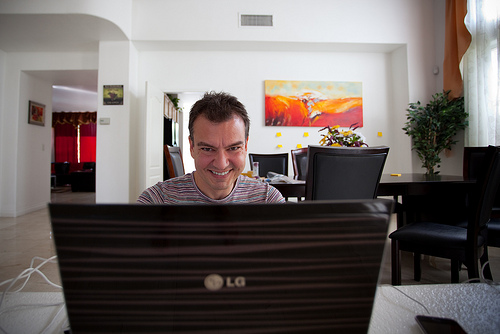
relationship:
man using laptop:
[129, 91, 293, 204] [52, 200, 385, 331]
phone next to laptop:
[413, 315, 471, 332] [52, 200, 385, 331]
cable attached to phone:
[377, 276, 434, 313] [413, 315, 470, 334]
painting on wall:
[265, 80, 362, 128] [144, 55, 398, 176]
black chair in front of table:
[390, 145, 500, 288] [260, 168, 496, 199]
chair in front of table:
[304, 143, 391, 196] [260, 168, 496, 199]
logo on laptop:
[198, 274, 245, 291] [52, 200, 385, 331]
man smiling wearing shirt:
[164, 101, 276, 196] [136, 171, 285, 203]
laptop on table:
[52, 200, 385, 331] [0, 281, 498, 331]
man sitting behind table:
[129, 91, 293, 204] [9, 207, 498, 321]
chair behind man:
[304, 145, 391, 200] [129, 88, 294, 204]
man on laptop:
[129, 88, 294, 204] [46, 191, 397, 331]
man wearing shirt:
[129, 88, 294, 204] [134, 170, 284, 200]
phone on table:
[413, 315, 470, 334] [371, 276, 498, 329]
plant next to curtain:
[403, 87, 470, 179] [433, 0, 477, 142]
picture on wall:
[28, 100, 45, 124] [17, 70, 52, 216]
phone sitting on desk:
[413, 315, 470, 334] [0, 290, 499, 331]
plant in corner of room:
[403, 87, 470, 180] [0, 2, 498, 330]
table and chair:
[380, 172, 475, 220] [307, 145, 389, 200]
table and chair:
[380, 172, 475, 220] [161, 145, 183, 176]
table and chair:
[380, 172, 475, 220] [247, 152, 291, 177]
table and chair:
[380, 172, 475, 220] [290, 146, 307, 178]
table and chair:
[380, 172, 475, 220] [461, 144, 490, 176]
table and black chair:
[380, 172, 475, 220] [390, 145, 500, 288]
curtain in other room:
[80, 115, 95, 161] [46, 84, 96, 204]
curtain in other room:
[51, 115, 94, 160] [46, 84, 96, 204]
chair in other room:
[66, 159, 96, 194] [46, 84, 96, 204]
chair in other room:
[49, 157, 71, 191] [46, 84, 96, 204]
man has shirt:
[129, 88, 294, 204] [136, 168, 288, 202]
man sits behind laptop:
[129, 88, 294, 204] [52, 200, 385, 331]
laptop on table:
[52, 200, 385, 331] [21, 186, 471, 332]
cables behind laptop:
[0, 247, 52, 301] [54, 189, 432, 326]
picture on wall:
[263, 77, 361, 127] [95, 10, 440, 252]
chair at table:
[304, 145, 391, 200] [338, 123, 498, 298]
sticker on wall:
[273, 129, 282, 137] [130, 0, 432, 205]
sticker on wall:
[373, 125, 391, 155] [168, 41, 403, 183]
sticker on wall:
[274, 144, 281, 149] [137, 49, 391, 200]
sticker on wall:
[275, 132, 282, 137] [167, 47, 388, 68]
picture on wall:
[102, 84, 124, 106] [132, 50, 439, 184]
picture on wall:
[259, 76, 370, 136] [19, 74, 56, 216]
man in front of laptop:
[129, 91, 293, 204] [52, 200, 385, 331]